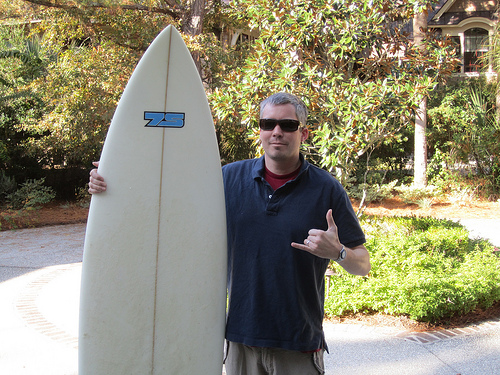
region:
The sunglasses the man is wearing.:
[251, 117, 301, 134]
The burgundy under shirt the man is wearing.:
[265, 163, 310, 183]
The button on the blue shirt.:
[265, 187, 275, 205]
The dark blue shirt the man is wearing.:
[214, 151, 389, 331]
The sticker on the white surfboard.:
[143, 106, 183, 131]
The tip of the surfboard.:
[122, 12, 201, 77]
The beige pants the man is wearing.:
[214, 334, 308, 374]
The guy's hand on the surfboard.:
[86, 155, 113, 197]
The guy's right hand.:
[291, 211, 347, 252]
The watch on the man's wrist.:
[334, 245, 351, 266]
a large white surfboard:
[79, 22, 226, 374]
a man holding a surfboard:
[75, 23, 370, 369]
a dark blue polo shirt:
[222, 154, 361, 355]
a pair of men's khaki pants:
[225, 342, 323, 374]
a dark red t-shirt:
[261, 165, 300, 192]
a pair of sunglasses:
[257, 115, 300, 135]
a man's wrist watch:
[333, 243, 348, 265]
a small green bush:
[322, 217, 496, 325]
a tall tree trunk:
[408, 0, 428, 188]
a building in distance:
[424, 0, 499, 87]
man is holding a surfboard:
[142, 26, 417, 373]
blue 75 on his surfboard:
[131, 102, 205, 140]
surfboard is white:
[79, 27, 308, 317]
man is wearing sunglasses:
[237, 103, 325, 141]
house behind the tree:
[400, 9, 488, 117]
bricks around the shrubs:
[365, 286, 496, 367]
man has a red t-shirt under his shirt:
[254, 150, 343, 194]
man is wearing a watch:
[331, 238, 382, 265]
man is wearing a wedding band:
[285, 224, 314, 258]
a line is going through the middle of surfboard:
[146, 12, 179, 372]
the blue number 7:
[144, 107, 166, 132]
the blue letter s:
[162, 110, 189, 131]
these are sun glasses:
[240, 105, 310, 146]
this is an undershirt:
[240, 145, 302, 206]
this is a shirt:
[176, 146, 399, 357]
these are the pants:
[198, 309, 345, 374]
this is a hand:
[273, 203, 353, 270]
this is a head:
[226, 78, 324, 190]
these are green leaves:
[383, 267, 430, 309]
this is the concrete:
[13, 265, 78, 317]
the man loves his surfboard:
[63, 21, 377, 373]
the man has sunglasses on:
[257, 119, 303, 136]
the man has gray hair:
[254, 92, 309, 163]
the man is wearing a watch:
[330, 241, 352, 268]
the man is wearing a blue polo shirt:
[223, 152, 370, 349]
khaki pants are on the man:
[223, 340, 326, 374]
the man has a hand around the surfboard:
[81, 27, 309, 212]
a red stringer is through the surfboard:
[144, 23, 175, 373]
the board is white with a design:
[76, 20, 227, 370]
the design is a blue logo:
[137, 102, 191, 135]